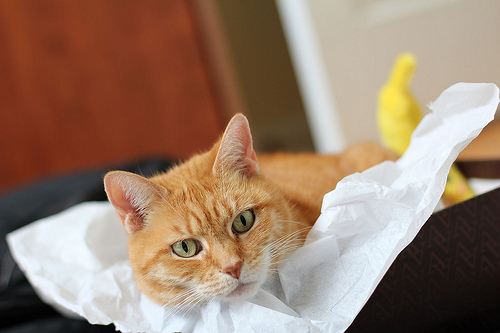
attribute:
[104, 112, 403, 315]
cat — on bag, orange, here, white, looking, lying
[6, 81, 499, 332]
bag — white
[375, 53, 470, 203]
toy — banana shaped, yellow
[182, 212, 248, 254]
pupils — oval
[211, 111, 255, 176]
ear — up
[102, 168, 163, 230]
ear — up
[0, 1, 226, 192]
door — wooden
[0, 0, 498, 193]
background — blurry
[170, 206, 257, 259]
eyes — green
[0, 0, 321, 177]
door way — open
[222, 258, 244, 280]
nose — pink